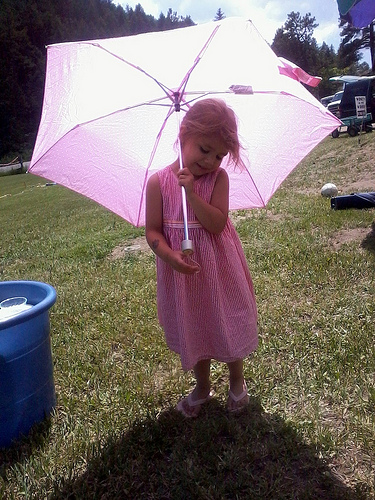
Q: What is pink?
A: Umbrella.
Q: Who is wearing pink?
A: Little girl.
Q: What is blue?
A: A bucket.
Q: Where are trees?
A: In the distance.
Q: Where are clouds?
A: In the sky.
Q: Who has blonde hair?
A: The girl.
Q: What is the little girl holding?
A: An umbrella.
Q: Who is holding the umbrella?
A: Little girl.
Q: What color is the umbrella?
A: Pink.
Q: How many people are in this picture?
A: 1.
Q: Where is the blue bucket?
A: On left side of girl.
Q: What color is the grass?
A: Green.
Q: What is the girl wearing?
A: A pink dress.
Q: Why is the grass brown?
A: Needs watering.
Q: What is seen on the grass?
A: Girl's shadow.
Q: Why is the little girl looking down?
A: Sees shadow.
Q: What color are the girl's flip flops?
A: Pink.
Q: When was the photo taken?
A: Afternoon.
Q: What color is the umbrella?
A: Pink.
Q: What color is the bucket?
A: Blue.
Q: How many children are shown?
A: One.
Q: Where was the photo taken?
A: Yard.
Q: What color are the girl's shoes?
A: Pink.